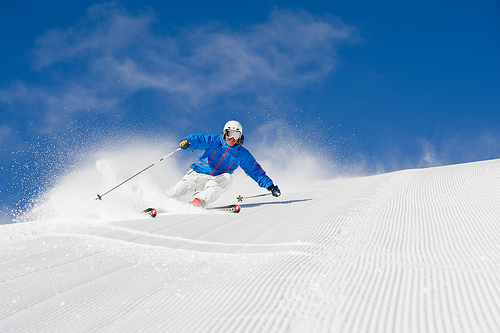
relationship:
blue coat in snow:
[141, 119, 280, 217] [324, 207, 467, 322]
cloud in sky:
[0, 0, 492, 224] [380, 30, 466, 95]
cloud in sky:
[0, 0, 492, 224] [2, 2, 497, 227]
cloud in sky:
[0, 0, 492, 224] [258, 29, 363, 91]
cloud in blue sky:
[0, 0, 492, 224] [2, 23, 497, 221]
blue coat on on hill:
[141, 119, 280, 217] [30, 127, 322, 184]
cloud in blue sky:
[0, 0, 492, 224] [0, 0, 494, 224]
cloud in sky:
[0, 0, 492, 224] [12, 42, 149, 128]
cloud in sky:
[0, 0, 492, 224] [1, 0, 498, 171]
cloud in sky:
[242, 9, 359, 89] [2, 2, 497, 227]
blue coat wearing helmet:
[141, 119, 280, 217] [218, 117, 241, 139]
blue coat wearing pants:
[141, 119, 280, 217] [153, 172, 234, 205]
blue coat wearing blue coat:
[141, 119, 280, 217] [173, 127, 280, 189]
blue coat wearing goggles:
[141, 119, 280, 217] [219, 125, 250, 142]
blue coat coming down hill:
[141, 119, 280, 217] [61, 110, 425, 288]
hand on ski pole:
[173, 137, 193, 147] [84, 139, 193, 206]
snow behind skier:
[11, 146, 170, 220] [147, 114, 284, 229]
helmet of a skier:
[215, 101, 255, 143] [72, 89, 336, 259]